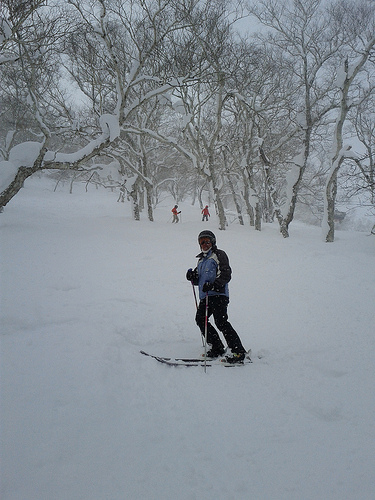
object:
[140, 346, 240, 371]
skis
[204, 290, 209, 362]
ski pole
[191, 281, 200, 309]
ski pole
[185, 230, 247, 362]
man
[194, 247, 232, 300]
jacket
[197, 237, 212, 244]
goggles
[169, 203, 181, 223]
person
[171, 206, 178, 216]
jacket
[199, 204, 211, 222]
person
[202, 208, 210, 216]
jacket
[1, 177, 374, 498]
snow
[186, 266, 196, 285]
glove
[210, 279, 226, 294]
glove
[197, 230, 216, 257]
head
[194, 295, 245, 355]
pants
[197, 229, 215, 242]
helmet